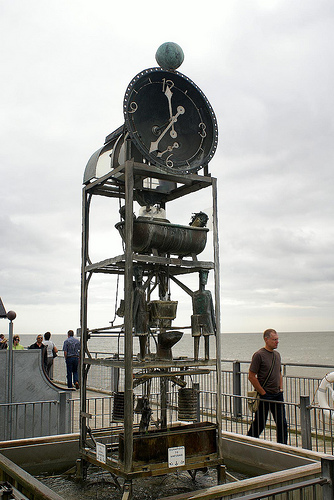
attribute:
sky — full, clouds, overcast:
[229, 51, 309, 149]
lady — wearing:
[25, 329, 55, 366]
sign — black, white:
[153, 450, 210, 471]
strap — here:
[249, 347, 295, 399]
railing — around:
[232, 397, 312, 455]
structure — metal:
[52, 73, 285, 411]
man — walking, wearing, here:
[206, 290, 325, 414]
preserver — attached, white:
[319, 369, 330, 399]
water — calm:
[214, 328, 260, 369]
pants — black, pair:
[240, 398, 301, 455]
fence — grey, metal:
[215, 355, 261, 409]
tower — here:
[87, 60, 215, 354]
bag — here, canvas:
[231, 384, 266, 416]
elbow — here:
[227, 358, 270, 390]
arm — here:
[235, 358, 303, 423]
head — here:
[250, 326, 301, 347]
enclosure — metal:
[6, 399, 107, 450]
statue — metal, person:
[88, 170, 239, 366]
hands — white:
[155, 94, 203, 149]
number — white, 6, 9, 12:
[135, 94, 244, 160]